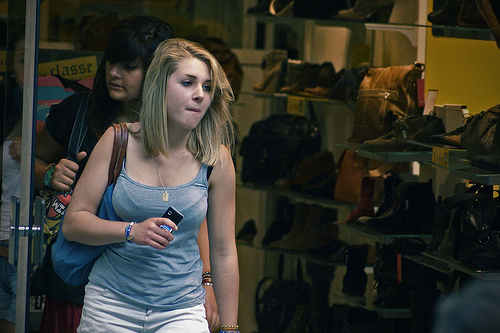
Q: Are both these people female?
A: Yes, all the people are female.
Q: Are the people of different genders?
A: No, all the people are female.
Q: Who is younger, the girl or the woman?
A: The girl is younger than the woman.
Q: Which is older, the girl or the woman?
A: The woman is older than the girl.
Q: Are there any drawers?
A: No, there are no drawers.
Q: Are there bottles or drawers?
A: No, there are no drawers or bottles.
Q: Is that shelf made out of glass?
A: Yes, the shelf is made of glass.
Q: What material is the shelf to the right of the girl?
A: The shelf is made of glass.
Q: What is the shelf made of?
A: The shelf is made of glass.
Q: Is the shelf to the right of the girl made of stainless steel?
A: No, the shelf is made of glass.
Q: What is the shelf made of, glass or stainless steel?
A: The shelf is made of glass.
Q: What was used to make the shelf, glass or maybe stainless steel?
A: The shelf is made of glass.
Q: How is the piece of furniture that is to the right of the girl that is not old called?
A: The piece of furniture is a shelf.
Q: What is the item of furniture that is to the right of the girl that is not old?
A: The piece of furniture is a shelf.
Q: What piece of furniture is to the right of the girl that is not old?
A: The piece of furniture is a shelf.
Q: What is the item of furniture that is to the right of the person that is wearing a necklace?
A: The piece of furniture is a shelf.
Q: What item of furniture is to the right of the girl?
A: The piece of furniture is a shelf.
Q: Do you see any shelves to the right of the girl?
A: Yes, there is a shelf to the right of the girl.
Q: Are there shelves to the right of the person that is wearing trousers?
A: Yes, there is a shelf to the right of the girl.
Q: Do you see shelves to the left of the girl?
A: No, the shelf is to the right of the girl.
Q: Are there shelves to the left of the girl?
A: No, the shelf is to the right of the girl.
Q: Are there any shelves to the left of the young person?
A: No, the shelf is to the right of the girl.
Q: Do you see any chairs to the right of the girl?
A: No, there is a shelf to the right of the girl.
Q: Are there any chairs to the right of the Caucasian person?
A: No, there is a shelf to the right of the girl.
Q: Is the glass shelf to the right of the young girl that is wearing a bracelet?
A: Yes, the shelf is to the right of the girl.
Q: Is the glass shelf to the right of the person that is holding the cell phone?
A: Yes, the shelf is to the right of the girl.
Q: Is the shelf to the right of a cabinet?
A: No, the shelf is to the right of the girl.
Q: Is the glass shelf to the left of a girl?
A: No, the shelf is to the right of a girl.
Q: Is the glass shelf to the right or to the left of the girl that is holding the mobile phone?
A: The shelf is to the right of the girl.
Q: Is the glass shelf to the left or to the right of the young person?
A: The shelf is to the right of the girl.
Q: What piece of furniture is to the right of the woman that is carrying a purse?
A: The piece of furniture is a shelf.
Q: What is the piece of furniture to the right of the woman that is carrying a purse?
A: The piece of furniture is a shelf.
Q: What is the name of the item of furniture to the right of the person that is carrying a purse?
A: The piece of furniture is a shelf.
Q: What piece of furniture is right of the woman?
A: The piece of furniture is a shelf.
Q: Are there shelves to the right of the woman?
A: Yes, there is a shelf to the right of the woman.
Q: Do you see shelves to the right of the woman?
A: Yes, there is a shelf to the right of the woman.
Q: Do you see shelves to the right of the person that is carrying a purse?
A: Yes, there is a shelf to the right of the woman.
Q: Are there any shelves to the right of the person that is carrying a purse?
A: Yes, there is a shelf to the right of the woman.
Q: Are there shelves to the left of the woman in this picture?
A: No, the shelf is to the right of the woman.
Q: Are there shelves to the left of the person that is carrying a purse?
A: No, the shelf is to the right of the woman.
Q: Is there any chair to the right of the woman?
A: No, there is a shelf to the right of the woman.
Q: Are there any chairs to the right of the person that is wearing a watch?
A: No, there is a shelf to the right of the woman.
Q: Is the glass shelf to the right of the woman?
A: Yes, the shelf is to the right of the woman.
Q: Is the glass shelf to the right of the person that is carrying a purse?
A: Yes, the shelf is to the right of the woman.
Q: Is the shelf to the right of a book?
A: No, the shelf is to the right of the woman.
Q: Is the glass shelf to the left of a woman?
A: No, the shelf is to the right of a woman.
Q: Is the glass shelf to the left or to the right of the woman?
A: The shelf is to the right of the woman.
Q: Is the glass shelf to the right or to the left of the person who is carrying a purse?
A: The shelf is to the right of the woman.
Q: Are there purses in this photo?
A: Yes, there is a purse.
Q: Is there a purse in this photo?
A: Yes, there is a purse.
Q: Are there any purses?
A: Yes, there is a purse.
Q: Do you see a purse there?
A: Yes, there is a purse.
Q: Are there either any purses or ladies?
A: Yes, there is a purse.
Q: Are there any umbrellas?
A: No, there are no umbrellas.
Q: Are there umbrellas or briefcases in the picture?
A: No, there are no umbrellas or briefcases.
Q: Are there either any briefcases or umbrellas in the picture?
A: No, there are no umbrellas or briefcases.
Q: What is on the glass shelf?
A: The purse is on the shelf.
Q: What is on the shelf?
A: The purse is on the shelf.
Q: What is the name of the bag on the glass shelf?
A: The bag is a purse.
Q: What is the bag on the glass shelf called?
A: The bag is a purse.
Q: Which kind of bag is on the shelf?
A: The bag is a purse.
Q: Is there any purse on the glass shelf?
A: Yes, there is a purse on the shelf.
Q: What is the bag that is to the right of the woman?
A: The bag is a purse.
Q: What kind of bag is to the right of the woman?
A: The bag is a purse.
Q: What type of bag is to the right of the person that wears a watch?
A: The bag is a purse.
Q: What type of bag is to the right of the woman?
A: The bag is a purse.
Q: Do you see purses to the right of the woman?
A: Yes, there is a purse to the right of the woman.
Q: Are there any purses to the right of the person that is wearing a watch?
A: Yes, there is a purse to the right of the woman.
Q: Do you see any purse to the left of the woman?
A: No, the purse is to the right of the woman.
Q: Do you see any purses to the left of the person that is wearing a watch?
A: No, the purse is to the right of the woman.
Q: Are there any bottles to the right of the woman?
A: No, there is a purse to the right of the woman.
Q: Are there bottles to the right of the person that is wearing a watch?
A: No, there is a purse to the right of the woman.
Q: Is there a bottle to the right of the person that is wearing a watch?
A: No, there is a purse to the right of the woman.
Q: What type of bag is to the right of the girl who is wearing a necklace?
A: The bag is a purse.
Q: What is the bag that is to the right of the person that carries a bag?
A: The bag is a purse.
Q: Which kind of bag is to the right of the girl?
A: The bag is a purse.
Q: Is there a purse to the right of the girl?
A: Yes, there is a purse to the right of the girl.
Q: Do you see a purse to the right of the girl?
A: Yes, there is a purse to the right of the girl.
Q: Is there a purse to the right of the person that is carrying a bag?
A: Yes, there is a purse to the right of the girl.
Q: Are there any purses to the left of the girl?
A: No, the purse is to the right of the girl.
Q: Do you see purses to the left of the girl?
A: No, the purse is to the right of the girl.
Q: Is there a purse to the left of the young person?
A: No, the purse is to the right of the girl.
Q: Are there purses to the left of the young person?
A: No, the purse is to the right of the girl.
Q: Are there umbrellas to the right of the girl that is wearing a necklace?
A: No, there is a purse to the right of the girl.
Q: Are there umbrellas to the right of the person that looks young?
A: No, there is a purse to the right of the girl.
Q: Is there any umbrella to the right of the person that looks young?
A: No, there is a purse to the right of the girl.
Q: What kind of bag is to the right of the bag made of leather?
A: The bag is a purse.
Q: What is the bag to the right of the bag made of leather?
A: The bag is a purse.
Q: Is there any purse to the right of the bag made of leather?
A: Yes, there is a purse to the right of the bag.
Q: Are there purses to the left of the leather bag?
A: No, the purse is to the right of the bag.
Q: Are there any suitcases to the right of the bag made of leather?
A: No, there is a purse to the right of the bag.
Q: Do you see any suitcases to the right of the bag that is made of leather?
A: No, there is a purse to the right of the bag.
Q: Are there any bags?
A: Yes, there is a bag.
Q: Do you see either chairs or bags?
A: Yes, there is a bag.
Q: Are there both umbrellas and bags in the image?
A: No, there is a bag but no umbrellas.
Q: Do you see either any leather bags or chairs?
A: Yes, there is a leather bag.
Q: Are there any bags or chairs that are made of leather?
A: Yes, the bag is made of leather.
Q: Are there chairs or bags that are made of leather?
A: Yes, the bag is made of leather.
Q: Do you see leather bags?
A: Yes, there is a bag that is made of leather.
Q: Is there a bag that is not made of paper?
A: Yes, there is a bag that is made of leather.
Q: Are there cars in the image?
A: No, there are no cars.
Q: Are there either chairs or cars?
A: No, there are no cars or chairs.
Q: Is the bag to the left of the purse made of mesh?
A: No, the bag is made of leather.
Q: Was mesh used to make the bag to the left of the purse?
A: No, the bag is made of leather.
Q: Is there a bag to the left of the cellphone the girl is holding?
A: Yes, there is a bag to the left of the cellphone.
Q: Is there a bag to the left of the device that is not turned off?
A: Yes, there is a bag to the left of the cellphone.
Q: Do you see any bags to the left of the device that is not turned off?
A: Yes, there is a bag to the left of the cellphone.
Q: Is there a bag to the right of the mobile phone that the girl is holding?
A: No, the bag is to the left of the mobile phone.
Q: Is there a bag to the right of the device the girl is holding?
A: No, the bag is to the left of the mobile phone.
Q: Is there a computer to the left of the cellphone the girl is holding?
A: No, there is a bag to the left of the mobile phone.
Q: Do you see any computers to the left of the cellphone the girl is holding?
A: No, there is a bag to the left of the mobile phone.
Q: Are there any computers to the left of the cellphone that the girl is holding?
A: No, there is a bag to the left of the mobile phone.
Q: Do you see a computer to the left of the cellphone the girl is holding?
A: No, there is a bag to the left of the mobile phone.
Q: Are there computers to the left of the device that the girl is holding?
A: No, there is a bag to the left of the mobile phone.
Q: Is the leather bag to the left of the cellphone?
A: Yes, the bag is to the left of the cellphone.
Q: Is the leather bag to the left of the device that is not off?
A: Yes, the bag is to the left of the cellphone.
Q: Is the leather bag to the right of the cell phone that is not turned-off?
A: No, the bag is to the left of the cell phone.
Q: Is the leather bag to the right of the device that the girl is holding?
A: No, the bag is to the left of the cell phone.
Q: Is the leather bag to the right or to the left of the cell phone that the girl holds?
A: The bag is to the left of the cell phone.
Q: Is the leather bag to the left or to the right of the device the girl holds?
A: The bag is to the left of the cell phone.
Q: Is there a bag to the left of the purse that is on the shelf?
A: Yes, there is a bag to the left of the purse.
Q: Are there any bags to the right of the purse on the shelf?
A: No, the bag is to the left of the purse.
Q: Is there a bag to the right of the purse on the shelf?
A: No, the bag is to the left of the purse.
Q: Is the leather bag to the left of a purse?
A: Yes, the bag is to the left of a purse.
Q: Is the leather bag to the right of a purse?
A: No, the bag is to the left of a purse.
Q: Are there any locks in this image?
A: No, there are no locks.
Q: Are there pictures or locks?
A: No, there are no locks or pictures.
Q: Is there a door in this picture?
A: Yes, there is a door.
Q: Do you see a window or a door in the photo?
A: Yes, there is a door.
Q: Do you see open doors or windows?
A: Yes, there is an open door.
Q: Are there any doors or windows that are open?
A: Yes, the door is open.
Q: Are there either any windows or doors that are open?
A: Yes, the door is open.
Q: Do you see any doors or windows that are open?
A: Yes, the door is open.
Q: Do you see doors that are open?
A: Yes, there is an open door.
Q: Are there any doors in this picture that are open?
A: Yes, there is a door that is open.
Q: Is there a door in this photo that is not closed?
A: Yes, there is a open door.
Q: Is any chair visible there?
A: No, there are no chairs.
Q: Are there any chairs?
A: No, there are no chairs.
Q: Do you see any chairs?
A: No, there are no chairs.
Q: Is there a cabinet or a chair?
A: No, there are no chairs or cabinets.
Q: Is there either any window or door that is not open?
A: No, there is a door but it is open.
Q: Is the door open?
A: Yes, the door is open.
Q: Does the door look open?
A: Yes, the door is open.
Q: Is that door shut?
A: No, the door is open.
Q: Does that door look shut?
A: No, the door is open.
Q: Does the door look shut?
A: No, the door is open.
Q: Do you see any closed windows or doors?
A: No, there is a door but it is open.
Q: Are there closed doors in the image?
A: No, there is a door but it is open.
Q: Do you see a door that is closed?
A: No, there is a door but it is open.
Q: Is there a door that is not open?
A: No, there is a door but it is open.